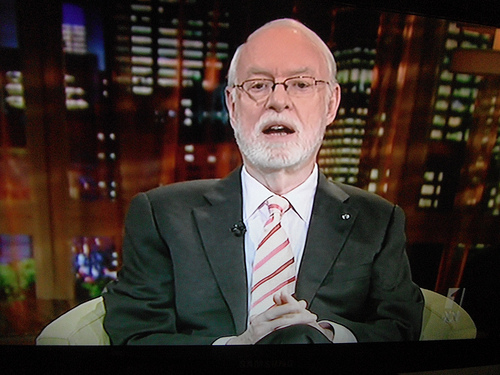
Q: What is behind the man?
A: A backdrop of a city.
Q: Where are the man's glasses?
A: Resting on his ears and nose.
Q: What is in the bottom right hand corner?
A: The logo of a television station.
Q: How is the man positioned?
A: He is seated in a chair.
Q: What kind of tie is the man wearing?
A: A striped tie.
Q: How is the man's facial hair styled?
A: His beard is neatly trimmed.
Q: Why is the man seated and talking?
A: He is a newscaster.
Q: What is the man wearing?
A: A suit and tie.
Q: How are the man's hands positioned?
A: They are interlocked and on his lap.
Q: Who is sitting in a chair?
A: A man.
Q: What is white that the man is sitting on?
A: Chair.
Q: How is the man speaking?
A: While looking directly ahead.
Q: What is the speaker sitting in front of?
A: City buildings.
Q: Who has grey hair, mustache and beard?
A: The man.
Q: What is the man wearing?
A: Dark gray suit with tie.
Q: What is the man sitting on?
A: Curved white chair.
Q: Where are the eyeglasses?
A: On the man's head.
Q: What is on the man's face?
A: Glasses.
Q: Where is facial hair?
A: On man's face.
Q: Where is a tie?
A: Around man's neck.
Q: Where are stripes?
A: On tie.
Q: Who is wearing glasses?
A: The man.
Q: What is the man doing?
A: Talking.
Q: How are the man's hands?
A: Folded.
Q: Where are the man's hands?
A: On man's lap.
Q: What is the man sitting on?
A: Chair.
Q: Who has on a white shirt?
A: A man.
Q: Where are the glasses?
A: On the man's face.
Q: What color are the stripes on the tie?
A: Pink.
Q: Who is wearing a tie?
A: Man.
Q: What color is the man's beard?
A: White.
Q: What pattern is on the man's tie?
A: Stripes.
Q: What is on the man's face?
A: Glasses.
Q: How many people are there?
A: 1.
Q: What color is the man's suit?
A: Black.